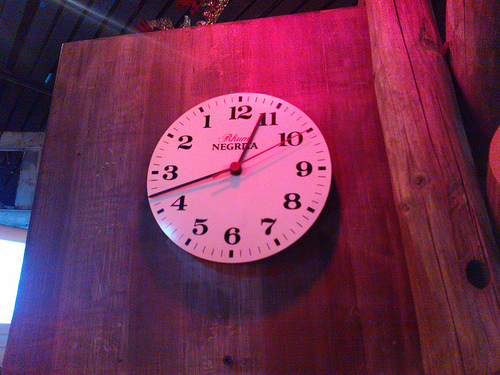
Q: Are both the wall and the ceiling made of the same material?
A: Yes, both the wall and the ceiling are made of wood.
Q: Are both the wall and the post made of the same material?
A: Yes, both the wall and the post are made of wood.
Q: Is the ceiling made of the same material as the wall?
A: Yes, both the ceiling and the wall are made of wood.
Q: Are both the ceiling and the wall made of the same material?
A: Yes, both the ceiling and the wall are made of wood.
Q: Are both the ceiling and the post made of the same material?
A: Yes, both the ceiling and the post are made of wood.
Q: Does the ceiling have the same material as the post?
A: Yes, both the ceiling and the post are made of wood.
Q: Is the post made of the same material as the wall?
A: Yes, both the post and the wall are made of wood.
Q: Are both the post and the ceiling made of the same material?
A: Yes, both the post and the ceiling are made of wood.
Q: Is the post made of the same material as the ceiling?
A: Yes, both the post and the ceiling are made of wood.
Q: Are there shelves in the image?
A: No, there are no shelves.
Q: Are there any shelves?
A: No, there are no shelves.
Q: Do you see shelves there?
A: No, there are no shelves.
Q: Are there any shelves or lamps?
A: No, there are no shelves or lamps.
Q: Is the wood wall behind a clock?
A: Yes, the wall is behind a clock.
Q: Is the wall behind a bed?
A: No, the wall is behind a clock.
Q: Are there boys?
A: No, there are no boys.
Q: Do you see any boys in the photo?
A: No, there are no boys.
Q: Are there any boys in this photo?
A: No, there are no boys.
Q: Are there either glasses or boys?
A: No, there are no boys or glasses.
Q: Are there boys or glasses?
A: No, there are no boys or glasses.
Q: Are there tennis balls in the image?
A: No, there are no tennis balls.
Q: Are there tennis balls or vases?
A: No, there are no tennis balls or vases.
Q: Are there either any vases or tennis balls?
A: No, there are no tennis balls or vases.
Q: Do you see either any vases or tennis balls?
A: No, there are no tennis balls or vases.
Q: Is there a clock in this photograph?
A: Yes, there is a clock.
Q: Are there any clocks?
A: Yes, there is a clock.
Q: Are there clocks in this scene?
A: Yes, there is a clock.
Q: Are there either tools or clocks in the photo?
A: Yes, there is a clock.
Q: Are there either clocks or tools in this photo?
A: Yes, there is a clock.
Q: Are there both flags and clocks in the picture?
A: No, there is a clock but no flags.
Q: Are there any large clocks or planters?
A: Yes, there is a large clock.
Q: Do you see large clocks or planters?
A: Yes, there is a large clock.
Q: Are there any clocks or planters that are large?
A: Yes, the clock is large.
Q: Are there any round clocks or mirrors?
A: Yes, there is a round clock.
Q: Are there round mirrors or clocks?
A: Yes, there is a round clock.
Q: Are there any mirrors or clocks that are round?
A: Yes, the clock is round.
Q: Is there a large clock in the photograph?
A: Yes, there is a large clock.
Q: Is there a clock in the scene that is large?
A: Yes, there is a clock that is large.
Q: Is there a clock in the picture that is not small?
A: Yes, there is a large clock.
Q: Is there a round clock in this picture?
A: Yes, there is a round clock.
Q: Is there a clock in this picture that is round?
A: Yes, there is a clock that is round.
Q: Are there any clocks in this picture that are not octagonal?
A: Yes, there is an round clock.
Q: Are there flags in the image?
A: No, there are no flags.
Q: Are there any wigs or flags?
A: No, there are no flags or wigs.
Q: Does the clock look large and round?
A: Yes, the clock is large and round.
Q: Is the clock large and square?
A: No, the clock is large but round.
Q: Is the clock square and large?
A: No, the clock is large but round.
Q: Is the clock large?
A: Yes, the clock is large.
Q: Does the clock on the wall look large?
A: Yes, the clock is large.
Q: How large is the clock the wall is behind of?
A: The clock is large.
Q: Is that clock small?
A: No, the clock is large.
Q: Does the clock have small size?
A: No, the clock is large.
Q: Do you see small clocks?
A: No, there is a clock but it is large.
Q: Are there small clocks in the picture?
A: No, there is a clock but it is large.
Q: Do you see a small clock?
A: No, there is a clock but it is large.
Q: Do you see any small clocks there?
A: No, there is a clock but it is large.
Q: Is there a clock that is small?
A: No, there is a clock but it is large.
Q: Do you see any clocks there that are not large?
A: No, there is a clock but it is large.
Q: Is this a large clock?
A: Yes, this is a large clock.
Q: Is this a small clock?
A: No, this is a large clock.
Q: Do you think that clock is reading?
A: Yes, the clock is reading.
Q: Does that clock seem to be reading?
A: Yes, the clock is reading.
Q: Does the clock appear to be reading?
A: Yes, the clock is reading.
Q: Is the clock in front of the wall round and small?
A: No, the clock is round but large.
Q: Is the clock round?
A: Yes, the clock is round.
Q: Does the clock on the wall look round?
A: Yes, the clock is round.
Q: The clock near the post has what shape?
A: The clock is round.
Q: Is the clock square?
A: No, the clock is round.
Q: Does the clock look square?
A: No, the clock is round.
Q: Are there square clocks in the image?
A: No, there is a clock but it is round.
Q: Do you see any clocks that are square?
A: No, there is a clock but it is round.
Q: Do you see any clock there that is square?
A: No, there is a clock but it is round.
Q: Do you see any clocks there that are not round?
A: No, there is a clock but it is round.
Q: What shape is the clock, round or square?
A: The clock is round.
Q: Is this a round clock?
A: Yes, this is a round clock.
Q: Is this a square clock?
A: No, this is a round clock.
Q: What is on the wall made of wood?
A: The clock is on the wall.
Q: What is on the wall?
A: The clock is on the wall.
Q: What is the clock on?
A: The clock is on the wall.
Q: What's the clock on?
A: The clock is on the wall.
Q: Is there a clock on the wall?
A: Yes, there is a clock on the wall.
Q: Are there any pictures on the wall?
A: No, there is a clock on the wall.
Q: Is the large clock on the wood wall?
A: Yes, the clock is on the wall.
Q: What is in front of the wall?
A: The clock is in front of the wall.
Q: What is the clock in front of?
A: The clock is in front of the wall.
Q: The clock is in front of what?
A: The clock is in front of the wall.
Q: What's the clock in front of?
A: The clock is in front of the wall.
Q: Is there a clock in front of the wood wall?
A: Yes, there is a clock in front of the wall.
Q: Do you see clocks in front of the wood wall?
A: Yes, there is a clock in front of the wall.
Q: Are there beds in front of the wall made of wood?
A: No, there is a clock in front of the wall.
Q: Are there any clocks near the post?
A: Yes, there is a clock near the post.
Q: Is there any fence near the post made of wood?
A: No, there is a clock near the post.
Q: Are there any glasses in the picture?
A: No, there are no glasses.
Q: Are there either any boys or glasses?
A: No, there are no glasses or boys.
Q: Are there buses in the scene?
A: No, there are no buses.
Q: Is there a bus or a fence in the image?
A: No, there are no buses or fences.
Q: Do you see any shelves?
A: No, there are no shelves.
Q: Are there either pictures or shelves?
A: No, there are no shelves or pictures.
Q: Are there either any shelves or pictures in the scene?
A: No, there are no shelves or pictures.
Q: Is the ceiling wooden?
A: Yes, the ceiling is wooden.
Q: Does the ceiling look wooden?
A: Yes, the ceiling is wooden.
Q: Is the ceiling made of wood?
A: Yes, the ceiling is made of wood.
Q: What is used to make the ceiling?
A: The ceiling is made of wood.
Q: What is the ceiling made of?
A: The ceiling is made of wood.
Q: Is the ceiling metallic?
A: No, the ceiling is wooden.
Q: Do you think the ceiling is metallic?
A: No, the ceiling is wooden.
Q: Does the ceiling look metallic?
A: No, the ceiling is wooden.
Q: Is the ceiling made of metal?
A: No, the ceiling is made of wood.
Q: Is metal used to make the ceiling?
A: No, the ceiling is made of wood.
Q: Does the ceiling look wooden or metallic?
A: The ceiling is wooden.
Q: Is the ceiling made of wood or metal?
A: The ceiling is made of wood.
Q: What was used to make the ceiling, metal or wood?
A: The ceiling is made of wood.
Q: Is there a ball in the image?
A: No, there are no balls.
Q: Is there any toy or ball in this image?
A: No, there are no balls or toys.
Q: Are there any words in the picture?
A: Yes, there are words.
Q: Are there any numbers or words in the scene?
A: Yes, there are words.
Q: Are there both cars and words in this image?
A: No, there are words but no cars.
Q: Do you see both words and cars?
A: No, there are words but no cars.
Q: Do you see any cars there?
A: No, there are no cars.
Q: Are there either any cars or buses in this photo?
A: No, there are no cars or buses.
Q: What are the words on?
A: The words are on the clock.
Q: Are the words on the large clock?
A: Yes, the words are on the clock.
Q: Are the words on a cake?
A: No, the words are on the clock.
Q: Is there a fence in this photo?
A: No, there are no fences.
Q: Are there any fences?
A: No, there are no fences.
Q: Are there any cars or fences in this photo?
A: No, there are no fences or cars.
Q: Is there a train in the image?
A: No, there are no trains.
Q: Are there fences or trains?
A: No, there are no trains or fences.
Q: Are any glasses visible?
A: No, there are no glasses.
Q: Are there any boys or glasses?
A: No, there are no glasses or boys.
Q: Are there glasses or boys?
A: No, there are no glasses or boys.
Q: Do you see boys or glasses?
A: No, there are no glasses or boys.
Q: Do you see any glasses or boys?
A: No, there are no glasses or boys.